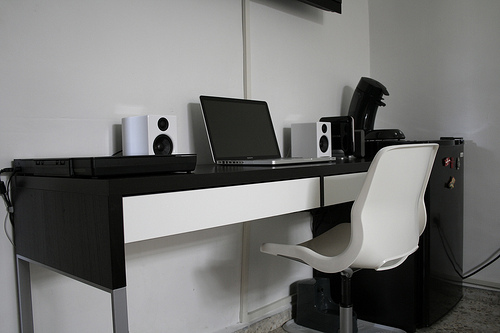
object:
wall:
[0, 0, 498, 138]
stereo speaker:
[121, 114, 177, 155]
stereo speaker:
[289, 121, 332, 160]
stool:
[258, 142, 440, 333]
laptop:
[196, 94, 337, 166]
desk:
[9, 161, 373, 333]